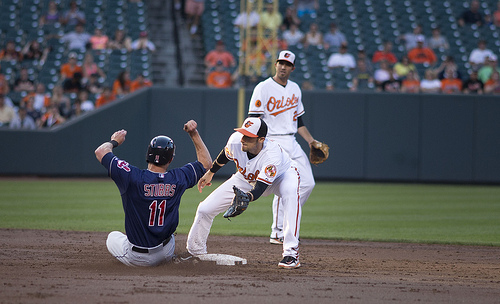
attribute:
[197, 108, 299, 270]
man — baseball player, light skinned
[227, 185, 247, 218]
glove — brown, black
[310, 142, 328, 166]
glove — brown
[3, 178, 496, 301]
field — grass, dirt, green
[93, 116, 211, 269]
man — sliding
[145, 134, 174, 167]
helmet — black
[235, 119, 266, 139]
hat — white, black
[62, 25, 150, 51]
spectators — blurry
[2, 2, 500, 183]
stands — dark green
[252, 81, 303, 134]
jersey — white, blue, orange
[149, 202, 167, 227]
11 — red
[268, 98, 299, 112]
lettering — orange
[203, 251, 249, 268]
base — white